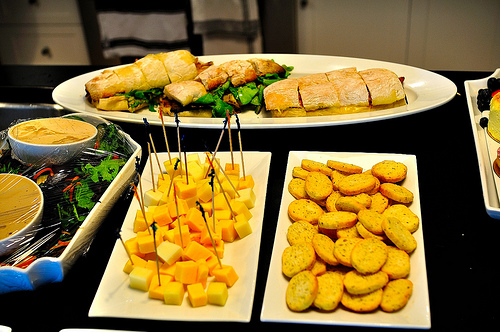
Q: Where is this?
A: This is at the kitchen.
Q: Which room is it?
A: It is a kitchen.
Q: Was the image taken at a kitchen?
A: Yes, it was taken in a kitchen.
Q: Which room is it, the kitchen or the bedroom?
A: It is the kitchen.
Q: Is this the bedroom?
A: No, it is the kitchen.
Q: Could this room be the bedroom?
A: No, it is the kitchen.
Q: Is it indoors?
A: Yes, it is indoors.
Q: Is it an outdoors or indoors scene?
A: It is indoors.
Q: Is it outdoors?
A: No, it is indoors.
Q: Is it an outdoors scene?
A: No, it is indoors.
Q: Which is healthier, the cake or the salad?
A: The salad is healthier than the cake.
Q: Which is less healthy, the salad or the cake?
A: The cake is less healthy than the salad.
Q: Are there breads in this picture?
A: Yes, there is a bread.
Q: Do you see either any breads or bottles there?
A: Yes, there is a bread.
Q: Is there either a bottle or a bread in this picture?
A: Yes, there is a bread.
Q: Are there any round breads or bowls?
A: Yes, there is a round bread.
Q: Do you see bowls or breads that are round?
A: Yes, the bread is round.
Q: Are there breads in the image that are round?
A: Yes, there is a bread that is round.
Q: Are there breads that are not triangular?
A: Yes, there is a round bread.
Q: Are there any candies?
A: No, there are no candies.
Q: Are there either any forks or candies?
A: No, there are no candies or forks.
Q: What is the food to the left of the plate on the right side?
A: The food is a bread.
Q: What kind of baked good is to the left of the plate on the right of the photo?
A: The food is a bread.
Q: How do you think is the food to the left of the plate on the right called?
A: The food is a bread.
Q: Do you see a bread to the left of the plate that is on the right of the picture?
A: Yes, there is a bread to the left of the plate.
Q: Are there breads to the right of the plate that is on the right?
A: No, the bread is to the left of the plate.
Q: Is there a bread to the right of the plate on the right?
A: No, the bread is to the left of the plate.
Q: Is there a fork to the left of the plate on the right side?
A: No, there is a bread to the left of the plate.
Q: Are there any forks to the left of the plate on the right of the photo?
A: No, there is a bread to the left of the plate.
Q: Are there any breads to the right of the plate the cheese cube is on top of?
A: Yes, there is a bread to the right of the plate.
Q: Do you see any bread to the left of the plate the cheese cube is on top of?
A: No, the bread is to the right of the plate.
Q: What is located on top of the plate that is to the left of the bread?
A: The cheese cube is on top of the plate.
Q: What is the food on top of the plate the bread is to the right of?
A: The food is a cheese cube.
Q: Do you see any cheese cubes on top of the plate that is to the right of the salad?
A: Yes, there is a cheese cube on top of the plate.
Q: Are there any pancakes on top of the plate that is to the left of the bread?
A: No, there is a cheese cube on top of the plate.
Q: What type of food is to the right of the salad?
A: The food is a cheese cube.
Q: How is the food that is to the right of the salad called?
A: The food is a cheese cube.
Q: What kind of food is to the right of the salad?
A: The food is a cheese cube.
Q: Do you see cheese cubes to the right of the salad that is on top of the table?
A: Yes, there is a cheese cube to the right of the salad.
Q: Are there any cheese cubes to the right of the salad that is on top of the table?
A: Yes, there is a cheese cube to the right of the salad.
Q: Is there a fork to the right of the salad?
A: No, there is a cheese cube to the right of the salad.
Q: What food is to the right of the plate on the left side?
A: The food is a cheese cube.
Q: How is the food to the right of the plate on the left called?
A: The food is a cheese cube.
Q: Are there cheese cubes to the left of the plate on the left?
A: No, the cheese cube is to the right of the plate.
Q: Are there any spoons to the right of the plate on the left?
A: No, there is a cheese cube to the right of the plate.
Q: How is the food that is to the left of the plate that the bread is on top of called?
A: The food is a cheese cube.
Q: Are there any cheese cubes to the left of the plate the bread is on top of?
A: Yes, there is a cheese cube to the left of the plate.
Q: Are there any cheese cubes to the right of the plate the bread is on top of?
A: No, the cheese cube is to the left of the plate.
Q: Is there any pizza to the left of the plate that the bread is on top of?
A: No, there is a cheese cube to the left of the plate.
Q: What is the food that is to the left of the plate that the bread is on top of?
A: The food is a cheese cube.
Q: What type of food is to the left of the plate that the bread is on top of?
A: The food is a cheese cube.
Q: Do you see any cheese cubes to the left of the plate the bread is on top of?
A: Yes, there is a cheese cube to the left of the plate.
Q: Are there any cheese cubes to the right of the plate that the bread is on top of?
A: No, the cheese cube is to the left of the plate.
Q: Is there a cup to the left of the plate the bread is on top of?
A: No, there is a cheese cube to the left of the plate.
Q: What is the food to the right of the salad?
A: The food is a cheese cube.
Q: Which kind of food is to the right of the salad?
A: The food is a cheese cube.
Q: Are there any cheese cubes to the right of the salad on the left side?
A: Yes, there is a cheese cube to the right of the salad.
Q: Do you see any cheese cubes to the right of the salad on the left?
A: Yes, there is a cheese cube to the right of the salad.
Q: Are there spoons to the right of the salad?
A: No, there is a cheese cube to the right of the salad.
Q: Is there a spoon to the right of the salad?
A: No, there is a cheese cube to the right of the salad.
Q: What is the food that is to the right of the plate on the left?
A: The food is a cheese cube.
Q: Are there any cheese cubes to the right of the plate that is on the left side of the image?
A: Yes, there is a cheese cube to the right of the plate.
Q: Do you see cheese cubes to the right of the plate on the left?
A: Yes, there is a cheese cube to the right of the plate.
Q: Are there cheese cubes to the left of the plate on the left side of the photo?
A: No, the cheese cube is to the right of the plate.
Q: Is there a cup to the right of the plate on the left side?
A: No, there is a cheese cube to the right of the plate.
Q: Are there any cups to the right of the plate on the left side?
A: No, there is a cheese cube to the right of the plate.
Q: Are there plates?
A: Yes, there is a plate.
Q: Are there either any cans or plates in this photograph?
A: Yes, there is a plate.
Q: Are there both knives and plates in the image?
A: No, there is a plate but no knives.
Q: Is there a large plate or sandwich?
A: Yes, there is a large plate.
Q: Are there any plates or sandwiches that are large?
A: Yes, the plate is large.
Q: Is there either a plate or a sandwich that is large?
A: Yes, the plate is large.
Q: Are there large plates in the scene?
A: Yes, there is a large plate.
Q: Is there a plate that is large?
A: Yes, there is a plate that is large.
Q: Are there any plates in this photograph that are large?
A: Yes, there is a plate that is large.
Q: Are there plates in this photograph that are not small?
A: Yes, there is a large plate.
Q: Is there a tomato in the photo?
A: No, there are no tomatoes.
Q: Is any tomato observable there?
A: No, there are no tomatoes.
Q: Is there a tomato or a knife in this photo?
A: No, there are no tomatoes or knives.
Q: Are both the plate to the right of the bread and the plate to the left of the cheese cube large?
A: Yes, both the plate and the plate are large.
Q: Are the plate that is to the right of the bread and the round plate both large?
A: Yes, both the plate and the plate are large.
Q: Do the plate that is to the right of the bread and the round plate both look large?
A: Yes, both the plate and the plate are large.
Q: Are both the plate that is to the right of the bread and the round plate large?
A: Yes, both the plate and the plate are large.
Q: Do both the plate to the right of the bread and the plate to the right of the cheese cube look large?
A: Yes, both the plate and the plate are large.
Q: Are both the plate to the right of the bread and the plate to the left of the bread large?
A: Yes, both the plate and the plate are large.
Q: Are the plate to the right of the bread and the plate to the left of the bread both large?
A: Yes, both the plate and the plate are large.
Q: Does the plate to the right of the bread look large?
A: Yes, the plate is large.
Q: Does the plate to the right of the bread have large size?
A: Yes, the plate is large.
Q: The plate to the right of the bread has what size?
A: The plate is large.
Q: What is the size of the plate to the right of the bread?
A: The plate is large.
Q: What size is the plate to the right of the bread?
A: The plate is large.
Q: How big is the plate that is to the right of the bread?
A: The plate is large.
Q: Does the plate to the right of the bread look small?
A: No, the plate is large.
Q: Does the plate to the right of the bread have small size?
A: No, the plate is large.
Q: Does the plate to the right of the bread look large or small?
A: The plate is large.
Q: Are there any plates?
A: Yes, there is a plate.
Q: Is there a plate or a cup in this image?
A: Yes, there is a plate.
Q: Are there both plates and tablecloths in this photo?
A: No, there is a plate but no tablecloths.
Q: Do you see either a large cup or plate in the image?
A: Yes, there is a large plate.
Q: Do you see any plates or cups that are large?
A: Yes, the plate is large.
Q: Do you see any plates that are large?
A: Yes, there is a large plate.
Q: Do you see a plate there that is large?
A: Yes, there is a plate that is large.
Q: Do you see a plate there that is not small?
A: Yes, there is a large plate.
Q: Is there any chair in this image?
A: No, there are no chairs.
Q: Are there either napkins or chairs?
A: No, there are no chairs or napkins.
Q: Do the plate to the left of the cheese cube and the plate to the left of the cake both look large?
A: Yes, both the plate and the plate are large.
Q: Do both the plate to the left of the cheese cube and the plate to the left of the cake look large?
A: Yes, both the plate and the plate are large.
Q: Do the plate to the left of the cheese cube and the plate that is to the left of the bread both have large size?
A: Yes, both the plate and the plate are large.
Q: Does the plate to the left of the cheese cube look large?
A: Yes, the plate is large.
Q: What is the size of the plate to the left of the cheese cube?
A: The plate is large.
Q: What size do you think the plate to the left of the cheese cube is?
A: The plate is large.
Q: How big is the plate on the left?
A: The plate is large.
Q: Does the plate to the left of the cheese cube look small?
A: No, the plate is large.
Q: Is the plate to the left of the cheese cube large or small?
A: The plate is large.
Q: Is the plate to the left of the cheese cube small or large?
A: The plate is large.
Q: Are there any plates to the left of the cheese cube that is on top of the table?
A: Yes, there is a plate to the left of the cheese cube.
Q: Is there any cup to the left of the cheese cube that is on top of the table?
A: No, there is a plate to the left of the cheese cube.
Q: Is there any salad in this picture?
A: Yes, there is salad.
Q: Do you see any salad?
A: Yes, there is salad.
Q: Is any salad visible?
A: Yes, there is salad.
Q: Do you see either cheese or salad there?
A: Yes, there is salad.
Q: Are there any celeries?
A: No, there are no celeries.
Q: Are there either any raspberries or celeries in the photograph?
A: No, there are no celeries or raspberries.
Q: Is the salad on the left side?
A: Yes, the salad is on the left of the image.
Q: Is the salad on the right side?
A: No, the salad is on the left of the image.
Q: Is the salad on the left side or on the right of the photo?
A: The salad is on the left of the image.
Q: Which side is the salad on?
A: The salad is on the left of the image.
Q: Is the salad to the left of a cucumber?
A: No, the salad is to the left of a cheese cube.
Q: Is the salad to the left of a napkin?
A: No, the salad is to the left of a cheese cube.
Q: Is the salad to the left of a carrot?
A: No, the salad is to the left of a cheese cube.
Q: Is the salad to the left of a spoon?
A: No, the salad is to the left of a cheese cube.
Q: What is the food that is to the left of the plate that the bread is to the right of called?
A: The food is salad.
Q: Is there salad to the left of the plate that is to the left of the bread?
A: Yes, there is salad to the left of the plate.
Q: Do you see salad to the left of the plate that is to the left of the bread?
A: Yes, there is salad to the left of the plate.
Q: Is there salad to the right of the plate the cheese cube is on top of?
A: No, the salad is to the left of the plate.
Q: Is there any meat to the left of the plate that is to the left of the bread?
A: No, there is salad to the left of the plate.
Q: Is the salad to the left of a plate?
A: Yes, the salad is to the left of a plate.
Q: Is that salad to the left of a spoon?
A: No, the salad is to the left of a plate.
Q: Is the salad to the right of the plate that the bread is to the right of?
A: No, the salad is to the left of the plate.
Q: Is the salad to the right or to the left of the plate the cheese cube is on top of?
A: The salad is to the left of the plate.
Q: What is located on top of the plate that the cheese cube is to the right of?
A: The salad is on top of the plate.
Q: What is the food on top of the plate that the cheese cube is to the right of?
A: The food is salad.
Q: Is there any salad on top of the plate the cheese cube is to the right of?
A: Yes, there is salad on top of the plate.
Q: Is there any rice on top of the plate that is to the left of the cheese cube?
A: No, there is salad on top of the plate.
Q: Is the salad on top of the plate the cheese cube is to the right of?
A: Yes, the salad is on top of the plate.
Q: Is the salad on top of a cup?
A: No, the salad is on top of the plate.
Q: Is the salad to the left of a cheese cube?
A: Yes, the salad is to the left of a cheese cube.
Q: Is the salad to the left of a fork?
A: No, the salad is to the left of a cheese cube.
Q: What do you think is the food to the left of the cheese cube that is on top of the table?
A: The food is salad.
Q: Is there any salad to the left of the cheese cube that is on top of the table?
A: Yes, there is salad to the left of the cheese cube.